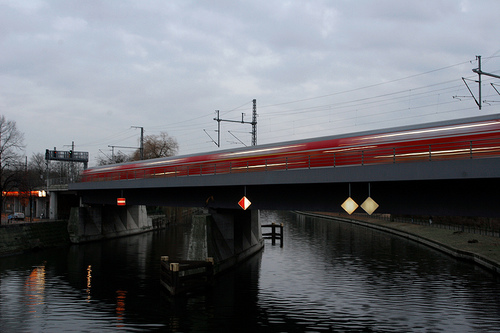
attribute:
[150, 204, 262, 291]
pillar — concrete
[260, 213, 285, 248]
gate — dark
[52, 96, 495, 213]
train — red, moving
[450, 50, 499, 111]
pole — electrical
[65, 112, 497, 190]
train — red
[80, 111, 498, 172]
train — red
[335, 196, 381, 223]
reflectors — diamond shaped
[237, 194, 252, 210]
sign — red, white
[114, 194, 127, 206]
sign — red, white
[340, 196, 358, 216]
sign — red, white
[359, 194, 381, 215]
sign — red, white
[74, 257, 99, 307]
reflection — light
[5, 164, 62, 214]
front — glowing, orange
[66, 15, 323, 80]
sky — cloudy, grey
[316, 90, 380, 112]
lines — electrical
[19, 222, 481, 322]
water — calm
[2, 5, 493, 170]
sky — overcast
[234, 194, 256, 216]
sign — square, red, white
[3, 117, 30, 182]
tree — bare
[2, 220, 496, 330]
water — calm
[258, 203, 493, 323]
water — calm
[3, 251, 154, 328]
water — calm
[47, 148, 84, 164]
lights — red, green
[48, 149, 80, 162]
light — black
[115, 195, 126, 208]
square — red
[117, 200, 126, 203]
stripe — white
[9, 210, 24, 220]
vehicle — white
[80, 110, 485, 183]
train — red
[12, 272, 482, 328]
water — dark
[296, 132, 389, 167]
blur — red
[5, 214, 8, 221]
person — blue, standing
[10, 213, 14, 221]
person — blue, standing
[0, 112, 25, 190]
tree — leafless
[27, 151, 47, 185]
tree — leafless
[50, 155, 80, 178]
tree — leafless